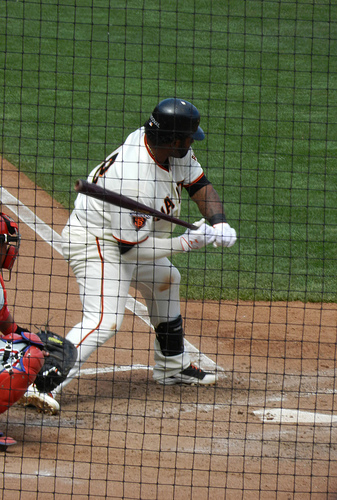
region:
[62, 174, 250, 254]
man holding a black bat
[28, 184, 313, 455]
the net is black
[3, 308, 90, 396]
the catcher`s glove is black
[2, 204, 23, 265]
the catcher`s mask is red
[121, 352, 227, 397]
the shoes are cleats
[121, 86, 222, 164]
the helmet is black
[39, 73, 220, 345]
the players uniform is white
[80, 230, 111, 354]
an orange line on the side of the pants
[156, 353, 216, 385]
the shoe laces are orange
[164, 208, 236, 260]
the player is wearing white gloves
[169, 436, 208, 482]
part of a ground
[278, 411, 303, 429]
part of a ground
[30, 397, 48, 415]
sole of a shoe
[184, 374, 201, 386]
edge of a shoe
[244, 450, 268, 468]
part of a cement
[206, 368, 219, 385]
part of a shoe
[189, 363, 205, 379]
part of a black part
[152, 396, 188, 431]
part of a line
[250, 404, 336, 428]
a small white base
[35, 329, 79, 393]
a dark baseball glove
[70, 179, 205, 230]
a dark baseball bat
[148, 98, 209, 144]
a dark baseball helmet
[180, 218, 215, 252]
white and red baseball gloves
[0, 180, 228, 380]
a white line on the baseball field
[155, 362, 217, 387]
a shoe of the baseball player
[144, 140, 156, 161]
a gold chain necklace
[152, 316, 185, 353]
protective ankle gear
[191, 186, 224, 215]
an arm tattoo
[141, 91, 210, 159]
the head of a man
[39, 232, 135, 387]
the leg of a man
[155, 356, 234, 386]
a white and black shoe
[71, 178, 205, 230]
a black baseball bat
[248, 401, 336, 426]
a white home plate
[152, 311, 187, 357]
a black shin guard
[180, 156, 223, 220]
the arm of a man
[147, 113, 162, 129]
white writing on the helmet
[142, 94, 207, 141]
a black helmet on the man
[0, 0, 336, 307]
a patch of green grass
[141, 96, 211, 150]
helmet on a player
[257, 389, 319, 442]
home plate under player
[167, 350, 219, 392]
cleat of a player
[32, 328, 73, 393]
mit of the catcher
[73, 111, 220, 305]
batter for the Giants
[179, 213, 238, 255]
white gloves on man's hand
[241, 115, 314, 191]
green grass on ground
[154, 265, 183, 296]
dirt on the player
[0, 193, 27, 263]
red mask on player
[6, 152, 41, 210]
third base line